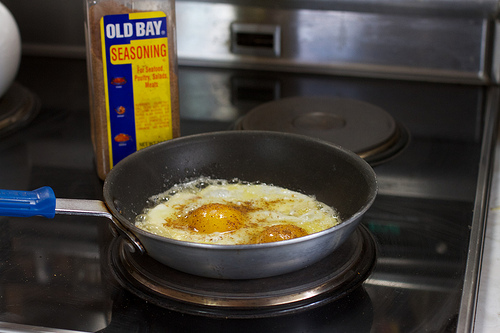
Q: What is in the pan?
A: Eggs.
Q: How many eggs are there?
A: 2.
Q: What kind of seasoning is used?
A: Oldbay.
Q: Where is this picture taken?
A: In a kitchen.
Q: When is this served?
A: For breakfast.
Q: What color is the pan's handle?
A: Blue.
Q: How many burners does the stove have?
A: 4.